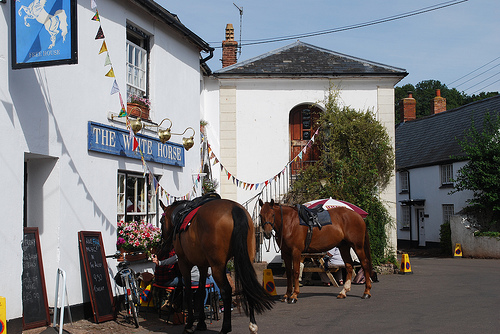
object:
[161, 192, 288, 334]
horse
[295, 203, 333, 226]
saddle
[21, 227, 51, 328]
chalkboard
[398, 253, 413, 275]
cone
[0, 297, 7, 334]
cone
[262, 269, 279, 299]
cone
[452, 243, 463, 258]
cone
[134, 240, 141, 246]
flowers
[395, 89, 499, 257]
building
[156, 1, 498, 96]
sky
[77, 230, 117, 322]
chalk board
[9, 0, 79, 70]
sign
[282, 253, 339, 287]
table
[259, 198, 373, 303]
horse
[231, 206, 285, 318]
black tail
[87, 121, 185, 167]
blue sign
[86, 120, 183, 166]
plaque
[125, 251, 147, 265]
box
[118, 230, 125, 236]
flowers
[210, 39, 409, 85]
roof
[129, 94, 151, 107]
flowers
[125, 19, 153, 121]
window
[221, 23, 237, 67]
chimney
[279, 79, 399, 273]
plant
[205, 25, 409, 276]
building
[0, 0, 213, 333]
building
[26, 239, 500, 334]
asphalt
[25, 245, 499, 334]
ground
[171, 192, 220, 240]
coat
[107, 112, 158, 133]
ledge